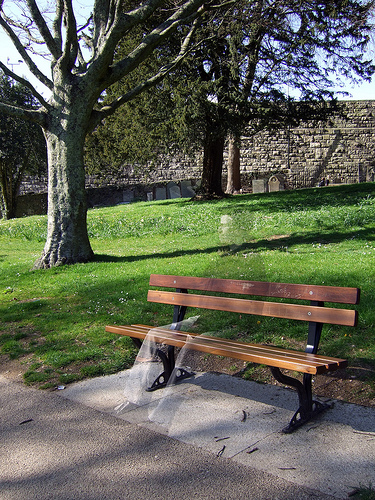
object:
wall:
[0, 101, 374, 218]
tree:
[0, 0, 280, 272]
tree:
[84, 0, 352, 202]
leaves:
[336, 76, 341, 81]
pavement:
[0, 370, 342, 498]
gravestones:
[155, 185, 167, 200]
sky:
[0, 0, 374, 103]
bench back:
[145, 272, 360, 327]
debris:
[216, 443, 226, 457]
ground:
[0, 182, 374, 499]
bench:
[104, 272, 361, 434]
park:
[0, 1, 374, 499]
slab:
[52, 361, 375, 499]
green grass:
[37, 379, 54, 390]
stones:
[308, 142, 321, 150]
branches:
[0, 60, 47, 107]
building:
[0, 99, 374, 218]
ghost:
[104, 209, 270, 448]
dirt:
[245, 233, 290, 245]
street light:
[18, 59, 24, 63]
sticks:
[247, 445, 259, 453]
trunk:
[48, 132, 86, 264]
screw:
[306, 310, 313, 316]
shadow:
[93, 218, 374, 262]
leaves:
[335, 78, 341, 82]